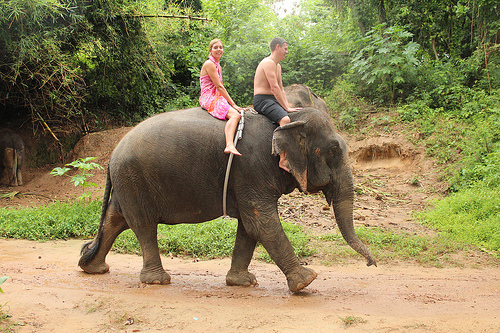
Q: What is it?
A: Elephant.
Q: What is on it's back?
A: People.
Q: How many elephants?
A: 1.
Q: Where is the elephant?
A: Road.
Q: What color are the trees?
A: Green.